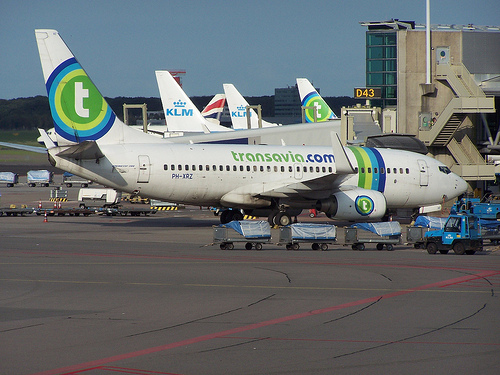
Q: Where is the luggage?
A: Luggage carts being towed.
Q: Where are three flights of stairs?
A: On side of building.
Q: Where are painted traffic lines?
A: On airfield.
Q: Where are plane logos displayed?
A: On tail sections.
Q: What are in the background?
A: A line of hills.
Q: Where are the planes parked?
A: On the tarmac.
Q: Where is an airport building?
A: On the right.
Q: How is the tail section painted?
A: Blue and green.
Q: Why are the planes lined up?
A: Waiting to be boarded.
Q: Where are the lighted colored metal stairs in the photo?
A: Right of airplane.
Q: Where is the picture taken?
A: An airport.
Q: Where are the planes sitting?
A: Gates.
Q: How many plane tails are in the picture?
A: 4.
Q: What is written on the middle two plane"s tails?
A: KLM.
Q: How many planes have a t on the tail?
A: Two.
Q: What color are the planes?
A: White.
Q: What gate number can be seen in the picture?
A: D43.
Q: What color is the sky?
A: Blue.